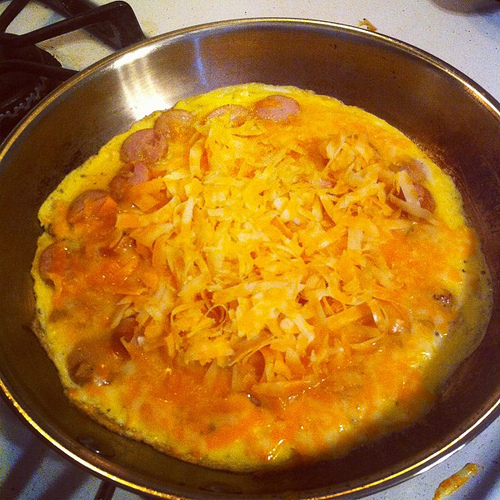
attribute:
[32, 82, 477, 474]
omelet — bright yellow, spread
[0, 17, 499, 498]
pan — gray, metal, shiny, steel, silver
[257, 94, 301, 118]
sausage — sliced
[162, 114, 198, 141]
sausage — brown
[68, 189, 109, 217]
sausage — sliced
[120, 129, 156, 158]
sausage — sliced, cut, circle, round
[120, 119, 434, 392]
cheese — grated, yellow, melted, orange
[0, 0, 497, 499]
stove — white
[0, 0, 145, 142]
burner — black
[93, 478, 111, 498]
burner — black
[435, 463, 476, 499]
omelet part — melting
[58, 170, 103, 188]
bubbles — small, dark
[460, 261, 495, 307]
bubbles — small, dark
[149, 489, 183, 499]
residue — brown